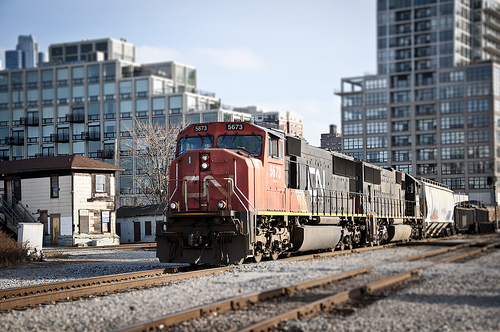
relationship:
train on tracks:
[173, 113, 299, 265] [108, 254, 168, 312]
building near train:
[358, 16, 482, 164] [173, 113, 299, 265]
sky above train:
[183, 10, 313, 67] [173, 113, 299, 265]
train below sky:
[173, 113, 299, 265] [183, 10, 313, 67]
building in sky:
[358, 16, 482, 164] [183, 10, 313, 67]